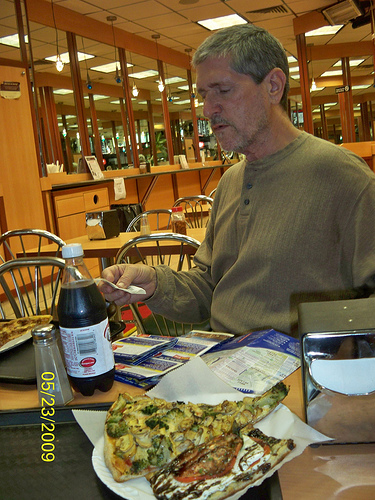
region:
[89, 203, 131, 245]
napkin dispenser on table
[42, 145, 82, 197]
straws in a box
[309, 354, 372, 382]
napkin is white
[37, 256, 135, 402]
bottle of soda on the table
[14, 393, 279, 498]
food tray is black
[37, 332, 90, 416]
pepper shaker on the table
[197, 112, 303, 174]
man has a beard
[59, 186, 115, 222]
trash cans under the counter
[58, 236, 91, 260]
bottle cap is white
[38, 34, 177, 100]
lights hanging from the ceiling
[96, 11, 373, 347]
a man sitting at table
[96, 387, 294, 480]
a slice of pizza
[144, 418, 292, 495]
a slice of pizza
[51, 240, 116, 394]
a bottle of soda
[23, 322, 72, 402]
a salt shaker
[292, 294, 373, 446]
a chrome napkin dispenser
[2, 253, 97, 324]
a chrome chair back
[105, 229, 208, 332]
a chrome chair back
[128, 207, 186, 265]
a chrome chair back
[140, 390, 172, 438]
a slice of pizza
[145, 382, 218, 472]
a slice of pizza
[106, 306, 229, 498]
a slice of pizza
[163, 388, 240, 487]
a slice of pizza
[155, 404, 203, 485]
a slice of pizza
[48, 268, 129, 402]
the bottle has soda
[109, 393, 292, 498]
two pieces of pizza are on plate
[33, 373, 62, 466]
the photo was taken in 2009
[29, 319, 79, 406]
the saltshaker is next to the bottle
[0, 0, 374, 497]
the guy is in a restaraunt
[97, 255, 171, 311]
the hand holds a paper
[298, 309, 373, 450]
the tin is silver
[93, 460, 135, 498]
the plate is white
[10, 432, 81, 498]
the tray is black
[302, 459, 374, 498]
the surface is wooden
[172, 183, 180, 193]
part of a stand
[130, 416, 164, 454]
part of some veges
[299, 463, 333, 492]
part of a floor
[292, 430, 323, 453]
edge of a paper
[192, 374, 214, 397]
part of a paper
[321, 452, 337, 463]
edge of a floor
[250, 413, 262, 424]
edge of a vege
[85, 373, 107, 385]
part of a bottle